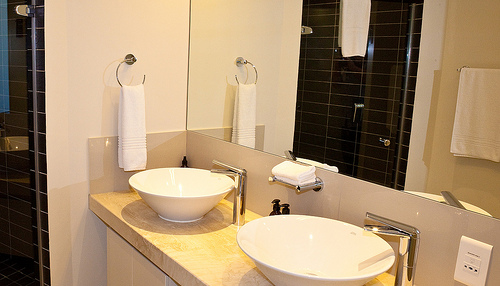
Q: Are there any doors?
A: Yes, there is a door.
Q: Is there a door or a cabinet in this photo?
A: Yes, there is a door.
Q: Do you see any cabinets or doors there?
A: Yes, there is a door.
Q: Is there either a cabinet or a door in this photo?
A: Yes, there is a door.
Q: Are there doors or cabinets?
A: Yes, there is a door.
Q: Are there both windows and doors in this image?
A: No, there is a door but no windows.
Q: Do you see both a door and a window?
A: No, there is a door but no windows.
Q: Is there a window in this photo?
A: No, there are no windows.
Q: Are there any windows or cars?
A: No, there are no windows or cars.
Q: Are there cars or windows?
A: No, there are no windows or cars.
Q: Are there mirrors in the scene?
A: Yes, there is a mirror.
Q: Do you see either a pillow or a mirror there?
A: Yes, there is a mirror.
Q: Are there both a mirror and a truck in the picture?
A: No, there is a mirror but no trucks.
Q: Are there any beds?
A: No, there are no beds.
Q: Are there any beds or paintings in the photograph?
A: No, there are no beds or paintings.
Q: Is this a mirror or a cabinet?
A: This is a mirror.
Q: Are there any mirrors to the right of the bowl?
A: Yes, there is a mirror to the right of the bowl.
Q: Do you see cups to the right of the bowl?
A: No, there is a mirror to the right of the bowl.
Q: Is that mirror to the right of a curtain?
A: No, the mirror is to the right of the bowl.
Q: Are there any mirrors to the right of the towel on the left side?
A: Yes, there is a mirror to the right of the towel.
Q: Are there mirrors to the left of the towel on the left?
A: No, the mirror is to the right of the towel.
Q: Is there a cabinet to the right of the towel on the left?
A: No, there is a mirror to the right of the towel.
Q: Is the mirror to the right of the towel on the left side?
A: Yes, the mirror is to the right of the towel.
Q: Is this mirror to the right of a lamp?
A: No, the mirror is to the right of the towel.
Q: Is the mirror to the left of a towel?
A: No, the mirror is to the right of a towel.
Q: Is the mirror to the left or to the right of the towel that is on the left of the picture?
A: The mirror is to the right of the towel.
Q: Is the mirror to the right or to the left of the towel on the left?
A: The mirror is to the right of the towel.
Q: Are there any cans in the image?
A: No, there are no cans.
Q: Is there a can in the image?
A: No, there are no cans.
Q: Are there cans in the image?
A: No, there are no cans.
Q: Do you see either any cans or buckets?
A: No, there are no cans or buckets.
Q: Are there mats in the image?
A: No, there are no mats.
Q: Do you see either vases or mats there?
A: No, there are no mats or vases.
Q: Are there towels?
A: Yes, there is a towel.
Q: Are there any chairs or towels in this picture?
A: Yes, there is a towel.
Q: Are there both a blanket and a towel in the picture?
A: No, there is a towel but no blankets.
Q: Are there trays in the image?
A: No, there are no trays.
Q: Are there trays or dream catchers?
A: No, there are no trays or dream catchers.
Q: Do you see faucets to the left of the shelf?
A: Yes, there is a faucet to the left of the shelf.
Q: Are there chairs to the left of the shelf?
A: No, there is a faucet to the left of the shelf.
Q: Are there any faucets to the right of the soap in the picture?
A: No, the faucet is to the left of the soap.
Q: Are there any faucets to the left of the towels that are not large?
A: Yes, there is a faucet to the left of the towels.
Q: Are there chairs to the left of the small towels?
A: No, there is a faucet to the left of the towels.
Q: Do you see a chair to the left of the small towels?
A: No, there is a faucet to the left of the towels.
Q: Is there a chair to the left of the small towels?
A: No, there is a faucet to the left of the towels.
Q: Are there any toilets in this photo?
A: No, there are no toilets.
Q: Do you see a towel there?
A: Yes, there is a towel.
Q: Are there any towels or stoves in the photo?
A: Yes, there is a towel.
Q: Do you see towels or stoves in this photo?
A: Yes, there is a towel.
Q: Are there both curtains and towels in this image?
A: No, there is a towel but no curtains.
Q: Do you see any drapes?
A: No, there are no drapes.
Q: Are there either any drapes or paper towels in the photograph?
A: No, there are no drapes or paper towels.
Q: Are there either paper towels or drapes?
A: No, there are no drapes or paper towels.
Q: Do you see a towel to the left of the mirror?
A: Yes, there is a towel to the left of the mirror.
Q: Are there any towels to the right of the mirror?
A: No, the towel is to the left of the mirror.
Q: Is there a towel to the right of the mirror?
A: No, the towel is to the left of the mirror.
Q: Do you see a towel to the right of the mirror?
A: No, the towel is to the left of the mirror.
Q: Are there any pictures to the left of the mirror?
A: No, there is a towel to the left of the mirror.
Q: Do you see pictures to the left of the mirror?
A: No, there is a towel to the left of the mirror.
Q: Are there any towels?
A: Yes, there is a towel.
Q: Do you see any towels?
A: Yes, there is a towel.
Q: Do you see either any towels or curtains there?
A: Yes, there is a towel.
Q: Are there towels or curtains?
A: Yes, there is a towel.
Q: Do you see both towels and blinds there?
A: No, there is a towel but no blinds.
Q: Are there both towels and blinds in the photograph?
A: No, there is a towel but no blinds.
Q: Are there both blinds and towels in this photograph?
A: No, there is a towel but no blinds.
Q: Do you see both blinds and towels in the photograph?
A: No, there is a towel but no blinds.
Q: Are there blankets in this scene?
A: No, there are no blankets.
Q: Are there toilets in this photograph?
A: No, there are no toilets.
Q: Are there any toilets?
A: No, there are no toilets.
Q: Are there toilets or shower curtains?
A: No, there are no toilets or shower curtains.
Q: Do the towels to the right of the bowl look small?
A: Yes, the towels are small.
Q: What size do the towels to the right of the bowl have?
A: The towels have small size.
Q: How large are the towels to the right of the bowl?
A: The towels are small.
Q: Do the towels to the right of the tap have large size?
A: No, the towels are small.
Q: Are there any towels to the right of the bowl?
A: Yes, there are towels to the right of the bowl.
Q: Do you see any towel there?
A: Yes, there is a towel.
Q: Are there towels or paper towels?
A: Yes, there is a towel.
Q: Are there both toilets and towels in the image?
A: No, there is a towel but no toilets.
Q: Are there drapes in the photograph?
A: No, there are no drapes.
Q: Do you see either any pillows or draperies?
A: No, there are no draperies or pillows.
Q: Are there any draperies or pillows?
A: No, there are no draperies or pillows.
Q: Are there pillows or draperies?
A: No, there are no draperies or pillows.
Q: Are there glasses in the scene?
A: No, there are no glasses.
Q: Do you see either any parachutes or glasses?
A: No, there are no glasses or parachutes.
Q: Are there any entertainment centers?
A: No, there are no entertainment centers.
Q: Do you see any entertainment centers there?
A: No, there are no entertainment centers.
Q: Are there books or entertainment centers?
A: No, there are no entertainment centers or books.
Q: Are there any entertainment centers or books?
A: No, there are no entertainment centers or books.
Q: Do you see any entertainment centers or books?
A: No, there are no entertainment centers or books.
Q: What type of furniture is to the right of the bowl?
A: The piece of furniture is a shelf.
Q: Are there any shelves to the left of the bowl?
A: No, the shelf is to the right of the bowl.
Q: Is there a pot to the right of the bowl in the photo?
A: No, there is a shelf to the right of the bowl.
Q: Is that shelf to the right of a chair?
A: No, the shelf is to the right of the bowl.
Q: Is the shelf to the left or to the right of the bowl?
A: The shelf is to the right of the bowl.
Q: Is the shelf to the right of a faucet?
A: Yes, the shelf is to the right of a faucet.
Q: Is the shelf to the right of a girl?
A: No, the shelf is to the right of a faucet.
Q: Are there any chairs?
A: No, there are no chairs.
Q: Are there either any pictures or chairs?
A: No, there are no chairs or pictures.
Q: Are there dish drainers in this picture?
A: No, there are no dish drainers.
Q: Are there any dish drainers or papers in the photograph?
A: No, there are no dish drainers or papers.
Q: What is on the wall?
A: The power outlet is on the wall.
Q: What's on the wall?
A: The power outlet is on the wall.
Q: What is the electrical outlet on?
A: The electrical outlet is on the wall.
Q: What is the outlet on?
A: The electrical outlet is on the wall.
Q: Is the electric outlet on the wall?
A: Yes, the electric outlet is on the wall.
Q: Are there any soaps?
A: Yes, there is a soap.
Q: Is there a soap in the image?
A: Yes, there is a soap.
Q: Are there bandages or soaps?
A: Yes, there is a soap.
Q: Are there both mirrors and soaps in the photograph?
A: Yes, there are both a soap and a mirror.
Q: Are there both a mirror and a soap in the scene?
A: Yes, there are both a soap and a mirror.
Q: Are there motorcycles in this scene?
A: No, there are no motorcycles.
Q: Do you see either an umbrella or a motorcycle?
A: No, there are no motorcycles or umbrellas.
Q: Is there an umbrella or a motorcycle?
A: No, there are no motorcycles or umbrellas.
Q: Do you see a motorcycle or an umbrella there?
A: No, there are no motorcycles or umbrellas.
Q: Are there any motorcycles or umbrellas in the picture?
A: No, there are no motorcycles or umbrellas.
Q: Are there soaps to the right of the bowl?
A: Yes, there is a soap to the right of the bowl.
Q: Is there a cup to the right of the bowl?
A: No, there is a soap to the right of the bowl.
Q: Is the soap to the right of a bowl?
A: Yes, the soap is to the right of a bowl.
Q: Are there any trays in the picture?
A: No, there are no trays.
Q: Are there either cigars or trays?
A: No, there are no trays or cigars.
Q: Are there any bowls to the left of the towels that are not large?
A: Yes, there is a bowl to the left of the towels.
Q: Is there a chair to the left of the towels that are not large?
A: No, there is a bowl to the left of the towels.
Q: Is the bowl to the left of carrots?
A: No, the bowl is to the left of the towels.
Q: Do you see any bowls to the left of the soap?
A: Yes, there is a bowl to the left of the soap.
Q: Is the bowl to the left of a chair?
A: No, the bowl is to the left of the soap.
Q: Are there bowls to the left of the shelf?
A: Yes, there is a bowl to the left of the shelf.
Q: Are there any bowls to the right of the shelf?
A: No, the bowl is to the left of the shelf.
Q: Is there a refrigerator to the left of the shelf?
A: No, there is a bowl to the left of the shelf.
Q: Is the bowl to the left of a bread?
A: No, the bowl is to the left of the shelf.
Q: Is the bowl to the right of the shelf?
A: No, the bowl is to the left of the shelf.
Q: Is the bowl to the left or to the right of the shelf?
A: The bowl is to the left of the shelf.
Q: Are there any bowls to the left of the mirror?
A: Yes, there is a bowl to the left of the mirror.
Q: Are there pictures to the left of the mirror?
A: No, there is a bowl to the left of the mirror.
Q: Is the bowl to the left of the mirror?
A: Yes, the bowl is to the left of the mirror.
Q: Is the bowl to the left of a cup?
A: No, the bowl is to the left of the mirror.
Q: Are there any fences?
A: No, there are no fences.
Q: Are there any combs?
A: No, there are no combs.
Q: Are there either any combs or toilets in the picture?
A: No, there are no combs or toilets.